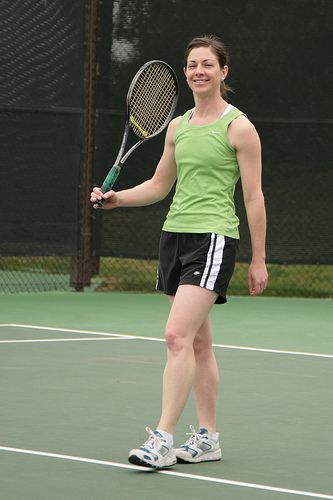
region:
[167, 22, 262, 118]
the head of a woman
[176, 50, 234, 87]
the eyes of a woman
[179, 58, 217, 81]
the nose of a woman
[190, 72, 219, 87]
the lips of a woman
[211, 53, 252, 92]
the ear of a woman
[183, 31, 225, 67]
the forehead of a woman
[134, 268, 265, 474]
the legs of a woman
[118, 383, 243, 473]
the feet of a woman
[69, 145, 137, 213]
woman holding a tennis racket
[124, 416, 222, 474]
woman wearing tennis shoes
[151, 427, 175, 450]
woman wearing white socks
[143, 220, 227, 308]
woman wearing black shorts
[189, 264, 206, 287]
logo on the shorts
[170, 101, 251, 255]
woman wearing a tank top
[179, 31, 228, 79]
woman with brown hair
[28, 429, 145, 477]
white lines on a tennis court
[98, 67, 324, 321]
woman on a tennis court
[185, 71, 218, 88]
woman with a smile on her face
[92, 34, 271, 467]
tennis player smiling for the camera.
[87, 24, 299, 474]
woman playing tennis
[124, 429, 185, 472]
foot hovering over the ground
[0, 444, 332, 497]
white line on the tennis court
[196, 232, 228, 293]
white lines on the side of the shorts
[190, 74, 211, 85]
smile on the face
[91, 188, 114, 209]
fingers wrapped around the handle of the racket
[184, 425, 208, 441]
shoelaces tied in a bow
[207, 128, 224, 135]
white nike logo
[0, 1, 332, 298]
tall chain link fence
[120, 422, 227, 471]
a pair of shoes on the feet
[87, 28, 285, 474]
A woman in the foreground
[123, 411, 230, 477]
Woman is wearing tennis shoes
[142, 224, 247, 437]
Woman is wearing black shorts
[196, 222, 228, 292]
Shorts have a white line on the side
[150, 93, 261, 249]
Woman is wearing a tank top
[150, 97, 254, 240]
The tank top is green in color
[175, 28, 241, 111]
Woman in the foreground is smiling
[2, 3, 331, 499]
Woman is on a tennis court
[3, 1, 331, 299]
A fence is in the background